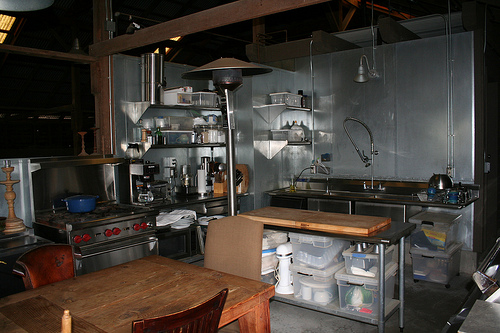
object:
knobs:
[71, 234, 85, 245]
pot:
[63, 194, 97, 214]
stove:
[50, 205, 141, 224]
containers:
[331, 261, 394, 316]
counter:
[239, 204, 413, 251]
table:
[0, 253, 277, 333]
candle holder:
[1, 157, 26, 235]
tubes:
[441, 6, 459, 171]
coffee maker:
[124, 160, 163, 211]